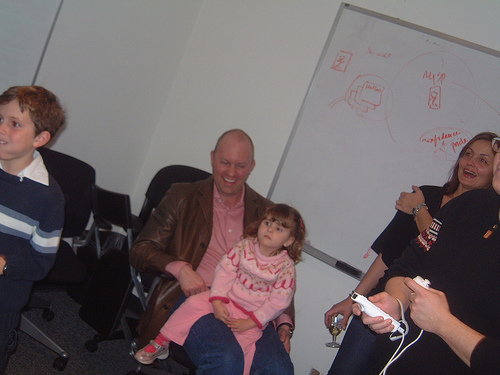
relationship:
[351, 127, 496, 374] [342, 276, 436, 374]
man holds wii remote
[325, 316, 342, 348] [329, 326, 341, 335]
glass contains beverage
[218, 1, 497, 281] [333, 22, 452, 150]
wall contains drawings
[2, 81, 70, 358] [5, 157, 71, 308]
boy wears shirt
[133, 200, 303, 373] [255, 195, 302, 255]
child with hair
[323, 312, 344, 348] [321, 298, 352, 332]
glass in a womans hand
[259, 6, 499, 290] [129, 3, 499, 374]
board on wall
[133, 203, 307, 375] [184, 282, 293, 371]
child sitting on lap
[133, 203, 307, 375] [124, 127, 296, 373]
child sitting with dad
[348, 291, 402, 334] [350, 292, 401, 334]
hand holding remote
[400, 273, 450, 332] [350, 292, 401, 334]
hand holding remote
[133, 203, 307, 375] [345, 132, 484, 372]
child watching person